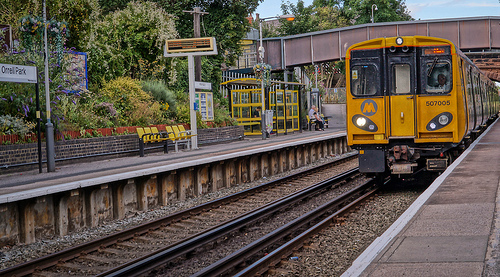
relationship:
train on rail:
[343, 26, 493, 190] [92, 188, 378, 277]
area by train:
[221, 61, 307, 134] [343, 26, 493, 190]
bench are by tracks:
[135, 124, 198, 156] [0, 154, 419, 272]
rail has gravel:
[92, 188, 378, 277] [12, 141, 417, 273]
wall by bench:
[16, 134, 155, 165] [123, 117, 190, 145]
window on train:
[351, 64, 377, 96] [342, 33, 470, 204]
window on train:
[411, 43, 461, 94] [320, 30, 498, 181]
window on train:
[394, 64, 411, 94] [348, 40, 462, 150]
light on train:
[411, 101, 443, 132] [332, 38, 462, 156]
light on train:
[380, 33, 416, 63] [342, 38, 464, 183]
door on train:
[387, 53, 417, 136] [318, 0, 498, 222]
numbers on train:
[418, 95, 465, 125] [329, 22, 498, 212]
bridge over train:
[296, 10, 498, 40] [332, 43, 495, 203]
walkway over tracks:
[256, 11, 473, 71] [203, 175, 404, 259]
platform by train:
[397, 126, 483, 275] [339, 38, 451, 185]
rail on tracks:
[244, 230, 314, 264] [128, 166, 404, 250]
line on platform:
[343, 185, 416, 273] [372, 153, 497, 269]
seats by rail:
[122, 130, 205, 151] [92, 188, 378, 277]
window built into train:
[351, 64, 377, 96] [343, 33, 484, 182]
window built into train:
[389, 60, 413, 91] [343, 33, 484, 182]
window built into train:
[426, 61, 451, 92] [343, 33, 484, 182]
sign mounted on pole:
[0, 60, 39, 83] [33, 80, 43, 172]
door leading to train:
[387, 55, 417, 136] [343, 33, 484, 182]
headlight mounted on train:
[355, 114, 365, 127] [343, 33, 484, 182]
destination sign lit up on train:
[420, 44, 448, 56] [343, 33, 484, 182]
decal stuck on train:
[360, 99, 378, 119] [343, 33, 484, 182]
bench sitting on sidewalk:
[135, 124, 198, 156] [0, 126, 346, 202]